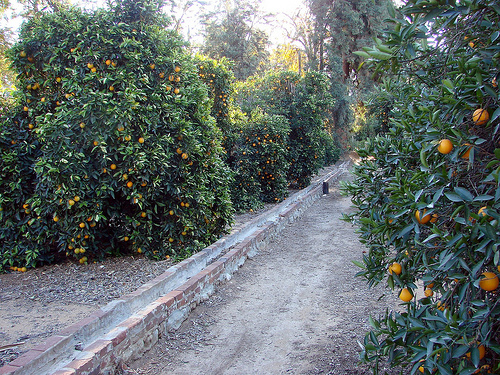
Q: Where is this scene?
A: Farm.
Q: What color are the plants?
A: Green.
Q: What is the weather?
A: Sunny.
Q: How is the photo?
A: Clear.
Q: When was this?
A: Daytime.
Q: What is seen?
A: Canal.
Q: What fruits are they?
A: Orange fruit.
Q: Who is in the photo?
A: No one.